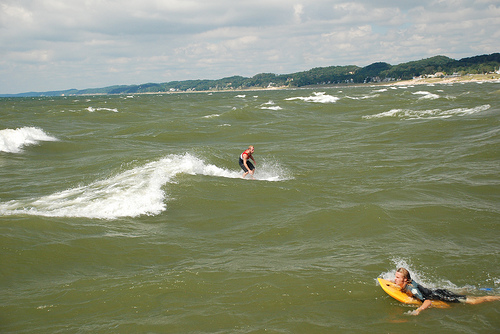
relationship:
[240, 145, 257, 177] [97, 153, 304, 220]
man surfing on wave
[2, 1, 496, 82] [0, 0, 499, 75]
sky with cloud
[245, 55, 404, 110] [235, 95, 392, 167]
hills behind ocean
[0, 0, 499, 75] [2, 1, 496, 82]
cloud in sky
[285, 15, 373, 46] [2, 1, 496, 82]
cloud in sky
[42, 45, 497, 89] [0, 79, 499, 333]
mountains near ocean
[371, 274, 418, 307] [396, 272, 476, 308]
board under man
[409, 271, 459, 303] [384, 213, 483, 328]
wetsuit on man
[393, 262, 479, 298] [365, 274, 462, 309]
man riding board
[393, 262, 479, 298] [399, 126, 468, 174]
man in water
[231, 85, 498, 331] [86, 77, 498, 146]
beach along shoreline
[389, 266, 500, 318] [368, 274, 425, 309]
man riding surfboard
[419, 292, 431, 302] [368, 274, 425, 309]
stomach on surfboard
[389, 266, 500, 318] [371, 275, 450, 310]
man lying on board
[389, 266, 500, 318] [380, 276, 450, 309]
man floating on surfboard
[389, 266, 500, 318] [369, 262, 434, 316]
man laying on surfboard